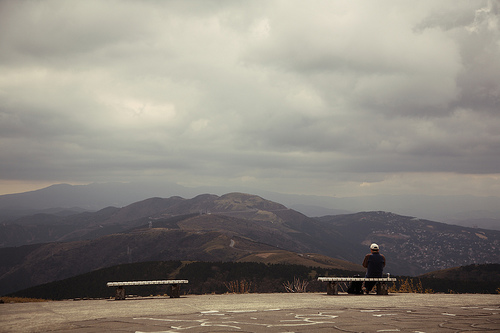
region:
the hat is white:
[362, 236, 388, 253]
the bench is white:
[108, 277, 190, 295]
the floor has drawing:
[207, 302, 372, 330]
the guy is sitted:
[362, 229, 412, 300]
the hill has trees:
[208, 256, 318, 298]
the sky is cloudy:
[181, 115, 407, 182]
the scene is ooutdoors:
[3, 93, 498, 330]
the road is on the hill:
[221, 232, 254, 249]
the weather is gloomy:
[6, 91, 498, 330]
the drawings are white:
[201, 304, 297, 331]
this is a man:
[354, 236, 384, 268]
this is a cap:
[367, 240, 384, 252]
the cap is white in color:
[371, 241, 378, 245]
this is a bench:
[111, 278, 186, 285]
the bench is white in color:
[101, 277, 181, 285]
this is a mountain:
[93, 195, 281, 245]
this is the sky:
[17, 32, 434, 178]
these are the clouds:
[148, 53, 249, 115]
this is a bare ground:
[215, 297, 275, 332]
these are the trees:
[221, 262, 251, 272]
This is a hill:
[26, 172, 87, 209]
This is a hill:
[79, 173, 126, 205]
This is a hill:
[130, 170, 176, 195]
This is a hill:
[32, 200, 67, 231]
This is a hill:
[89, 195, 121, 220]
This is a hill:
[140, 186, 163, 216]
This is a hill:
[162, 186, 180, 214]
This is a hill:
[191, 182, 221, 218]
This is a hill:
[226, 182, 292, 227]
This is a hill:
[326, 201, 399, 229]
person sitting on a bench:
[365, 244, 387, 276]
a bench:
[106, 279, 192, 296]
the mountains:
[131, 188, 398, 254]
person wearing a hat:
[368, 241, 381, 250]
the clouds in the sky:
[128, 50, 480, 168]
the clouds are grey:
[128, 56, 386, 156]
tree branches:
[283, 278, 310, 294]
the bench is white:
[107, 280, 198, 287]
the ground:
[178, 298, 365, 330]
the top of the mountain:
[158, 185, 252, 207]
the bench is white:
[108, 270, 206, 308]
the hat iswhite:
[366, 241, 392, 261]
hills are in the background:
[55, 188, 475, 261]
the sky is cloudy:
[14, 4, 497, 184]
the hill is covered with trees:
[181, 260, 317, 295]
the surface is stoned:
[8, 299, 492, 331]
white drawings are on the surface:
[172, 296, 274, 331]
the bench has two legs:
[104, 274, 217, 327]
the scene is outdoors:
[3, 5, 498, 317]